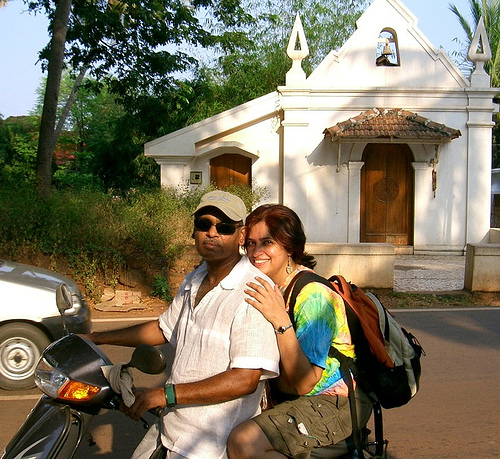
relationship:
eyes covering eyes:
[191, 209, 242, 235] [191, 209, 242, 240]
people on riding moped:
[66, 189, 375, 456] [2, 287, 387, 457]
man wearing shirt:
[67, 188, 282, 449] [143, 248, 282, 388]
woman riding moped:
[234, 196, 377, 454] [6, 311, 416, 457]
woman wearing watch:
[224, 201, 374, 457] [270, 320, 298, 334]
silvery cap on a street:
[7, 336, 45, 386] [25, 292, 484, 456]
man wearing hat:
[67, 188, 282, 449] [191, 185, 249, 225]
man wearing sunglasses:
[67, 188, 282, 449] [193, 216, 246, 239]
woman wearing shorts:
[224, 201, 374, 457] [251, 382, 374, 454]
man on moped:
[67, 193, 261, 449] [2, 282, 387, 456]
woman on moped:
[234, 196, 377, 454] [2, 282, 387, 456]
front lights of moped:
[25, 357, 100, 404] [11, 332, 378, 452]